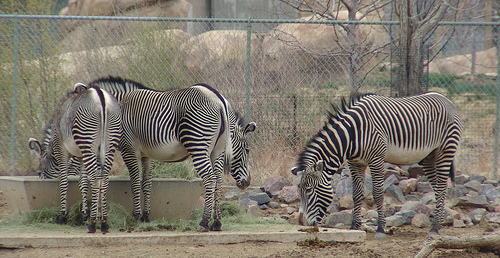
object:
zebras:
[28, 75, 258, 234]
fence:
[0, 15, 500, 187]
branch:
[416, 237, 500, 255]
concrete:
[0, 224, 366, 255]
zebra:
[290, 91, 463, 236]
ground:
[0, 234, 500, 258]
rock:
[183, 30, 264, 103]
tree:
[290, 0, 449, 97]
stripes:
[136, 100, 171, 142]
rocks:
[0, 0, 500, 84]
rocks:
[218, 155, 500, 231]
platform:
[0, 222, 369, 244]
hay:
[0, 0, 499, 184]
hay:
[0, 198, 296, 238]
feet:
[196, 219, 223, 233]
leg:
[368, 145, 387, 243]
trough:
[0, 174, 204, 218]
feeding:
[24, 147, 125, 205]